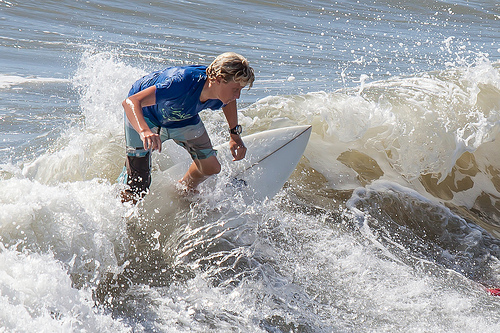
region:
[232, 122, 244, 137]
The watch on the surfer's wrist.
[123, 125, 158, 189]
The left leg of the shorts.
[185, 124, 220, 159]
The right leg of the shorts.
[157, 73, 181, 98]
The left sleeve of the blue t-shirt.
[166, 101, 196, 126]
The design on the front of the blue t-shirt.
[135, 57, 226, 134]
The blue t-shirt the surfer is wearing.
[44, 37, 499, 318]
The waves surrounding the surfer.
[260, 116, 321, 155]
The tip of the surfboard.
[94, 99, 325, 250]
The white surfboard the surfer is riding.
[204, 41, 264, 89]
The blonde hair of the surfer.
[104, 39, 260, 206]
The person on the board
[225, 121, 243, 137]
Watch on the surfer's wrist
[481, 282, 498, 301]
Red object in the water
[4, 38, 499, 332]
The wave being ridden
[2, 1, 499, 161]
Calm water behind the wave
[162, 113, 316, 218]
The white surfboard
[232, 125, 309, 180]
The line down the middle of the board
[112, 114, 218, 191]
Shorts the surfer is wearing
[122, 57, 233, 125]
Blue shirt worn by the surfer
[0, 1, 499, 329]
The ocean of brown water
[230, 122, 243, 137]
The watch on the surfer's right wrist.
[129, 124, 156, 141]
The left wrist of the surfer.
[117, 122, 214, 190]
The shorts the surfer is wearing.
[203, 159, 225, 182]
The right knee of the surfer.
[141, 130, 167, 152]
The left hand of the surfer.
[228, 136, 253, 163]
The right hand of the surfer.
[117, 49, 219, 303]
This is a man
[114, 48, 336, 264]
This man is water surfing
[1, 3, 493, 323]
This is a big mass of water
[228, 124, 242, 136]
This is a wrist watch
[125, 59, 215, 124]
This is a blue tshirt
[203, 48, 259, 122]
This is a head of a man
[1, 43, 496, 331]
This water is splashing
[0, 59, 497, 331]
This water is very clean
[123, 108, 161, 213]
This is right leg of a man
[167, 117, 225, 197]
This is the left leg of a man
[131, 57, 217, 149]
Surfer wearing blue shirt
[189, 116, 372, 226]
White surfboard in water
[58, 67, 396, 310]
Surfer is riding waves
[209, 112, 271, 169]
Black wristwatch on surfer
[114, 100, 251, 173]
Surfer wearing board shorts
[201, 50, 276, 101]
Surfer has short blond hair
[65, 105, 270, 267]
Surfer has both legs on surfboard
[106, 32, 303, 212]
Surfer is leaning forward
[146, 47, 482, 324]
Surfer is riding small wave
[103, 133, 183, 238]
surfer wearing knee brace